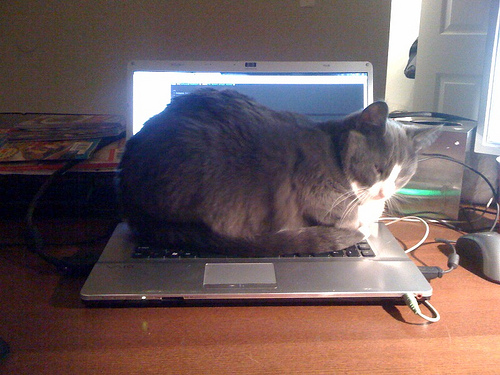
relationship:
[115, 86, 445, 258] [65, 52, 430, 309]
cat standing on a laptop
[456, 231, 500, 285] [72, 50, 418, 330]
mouse of a laptop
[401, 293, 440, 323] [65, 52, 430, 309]
cord connected to laptop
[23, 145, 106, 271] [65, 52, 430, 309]
cable of laptop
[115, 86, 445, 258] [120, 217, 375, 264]
cat lying on keyboard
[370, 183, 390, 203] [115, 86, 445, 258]
nose of cat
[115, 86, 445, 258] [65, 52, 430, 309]
cat sleeping on laptop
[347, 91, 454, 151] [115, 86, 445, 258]
ears of a cat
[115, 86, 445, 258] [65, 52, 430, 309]
cat sleeping on a laptop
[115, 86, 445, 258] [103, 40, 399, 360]
cat on laptop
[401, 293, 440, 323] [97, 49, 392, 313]
cord in computer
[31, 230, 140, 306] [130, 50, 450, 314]
cord in computer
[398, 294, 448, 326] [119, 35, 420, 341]
cord in laptop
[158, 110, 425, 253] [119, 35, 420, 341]
cat on laptop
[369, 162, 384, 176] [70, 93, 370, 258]
eye on cat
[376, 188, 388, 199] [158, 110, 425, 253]
nose on cat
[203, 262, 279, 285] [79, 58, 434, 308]
mouse pad on computer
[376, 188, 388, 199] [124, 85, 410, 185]
nose on cat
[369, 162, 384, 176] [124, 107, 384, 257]
eye on cat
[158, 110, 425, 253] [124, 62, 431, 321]
cat on laptop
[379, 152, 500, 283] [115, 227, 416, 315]
cord to laptop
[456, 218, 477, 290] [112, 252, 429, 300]
mouse of laptop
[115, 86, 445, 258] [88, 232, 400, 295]
cat on laptop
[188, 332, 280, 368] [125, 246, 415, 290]
desk under laptop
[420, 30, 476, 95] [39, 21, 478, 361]
door to room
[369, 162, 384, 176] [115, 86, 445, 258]
eye on cat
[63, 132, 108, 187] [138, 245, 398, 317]
cable to laptop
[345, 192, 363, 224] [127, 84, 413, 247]
whiskers on a cat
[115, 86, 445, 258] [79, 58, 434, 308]
cat sleeping on computer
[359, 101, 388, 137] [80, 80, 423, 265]
ear of cat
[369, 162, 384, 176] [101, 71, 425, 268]
eye of cat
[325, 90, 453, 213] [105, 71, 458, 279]
head of cat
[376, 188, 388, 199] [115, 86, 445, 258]
nose of cat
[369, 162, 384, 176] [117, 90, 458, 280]
eye of cat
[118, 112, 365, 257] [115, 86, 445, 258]
leg of cat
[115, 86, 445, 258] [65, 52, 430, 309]
cat on laptop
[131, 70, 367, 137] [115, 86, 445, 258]
screen blocked by cat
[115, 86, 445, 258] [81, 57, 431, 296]
cat on laptop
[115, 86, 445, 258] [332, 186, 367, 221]
cat with whiskers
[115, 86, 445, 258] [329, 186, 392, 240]
cat with whiskers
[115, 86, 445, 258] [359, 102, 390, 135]
cat with ear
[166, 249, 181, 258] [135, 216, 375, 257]
button on keyboard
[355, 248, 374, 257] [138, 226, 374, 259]
button on keyboard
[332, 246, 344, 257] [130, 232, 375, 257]
button on keyboard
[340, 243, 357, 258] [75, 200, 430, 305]
button on keyboard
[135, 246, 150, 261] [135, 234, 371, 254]
button on keyboard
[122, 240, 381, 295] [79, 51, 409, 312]
keyboard of a computer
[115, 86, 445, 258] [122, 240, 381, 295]
cat sitting on keyboard